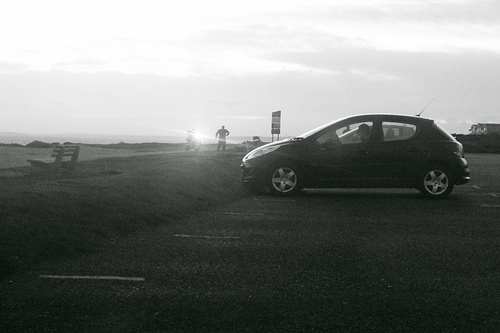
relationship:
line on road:
[27, 262, 185, 294] [192, 219, 401, 301]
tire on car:
[267, 163, 304, 196] [240, 98, 471, 200]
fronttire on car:
[232, 109, 470, 201] [240, 98, 471, 200]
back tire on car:
[413, 153, 479, 209] [240, 98, 471, 200]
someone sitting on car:
[357, 124, 371, 143] [216, 105, 486, 211]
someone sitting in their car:
[353, 122, 373, 145] [240, 98, 471, 200]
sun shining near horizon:
[193, 132, 204, 149] [110, 131, 272, 158]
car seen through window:
[240, 98, 471, 200] [336, 122, 374, 145]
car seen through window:
[240, 98, 471, 200] [382, 121, 417, 141]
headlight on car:
[240, 143, 275, 164] [240, 98, 471, 200]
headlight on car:
[248, 145, 282, 160] [240, 98, 471, 200]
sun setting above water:
[194, 132, 204, 138] [1, 131, 295, 145]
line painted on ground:
[38, 275, 145, 282] [6, 142, 497, 331]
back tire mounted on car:
[416, 163, 454, 200] [240, 98, 471, 200]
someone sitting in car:
[357, 124, 371, 143] [240, 98, 471, 200]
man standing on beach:
[214, 123, 229, 152] [3, 140, 266, 174]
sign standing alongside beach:
[265, 107, 290, 139] [3, 149, 212, 171]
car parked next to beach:
[216, 105, 486, 211] [42, 138, 232, 290]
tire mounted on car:
[267, 163, 304, 196] [240, 98, 471, 200]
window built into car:
[314, 118, 372, 143] [240, 98, 471, 200]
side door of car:
[316, 118, 383, 187] [240, 98, 471, 200]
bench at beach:
[28, 144, 81, 172] [3, 140, 266, 174]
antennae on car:
[413, 97, 435, 118] [240, 98, 471, 200]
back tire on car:
[416, 163, 454, 200] [240, 98, 471, 200]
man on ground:
[216, 126, 230, 152] [6, 142, 497, 331]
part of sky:
[100, 71, 163, 117] [2, 3, 499, 119]